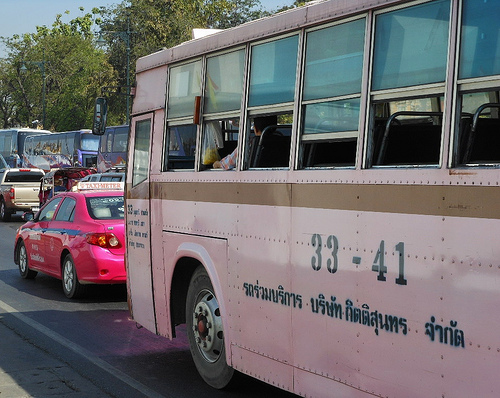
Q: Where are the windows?
A: On the side of the bus.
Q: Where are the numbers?
A: On the side of the bus.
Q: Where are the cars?
A: In the street.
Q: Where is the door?
A: At the front of the bus.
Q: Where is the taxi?
A: In front of the bus.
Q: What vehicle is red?
A: The taxi.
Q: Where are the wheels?
A: On the vehicle.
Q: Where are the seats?
A: Inside the bus.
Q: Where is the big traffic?
A: On a busy street.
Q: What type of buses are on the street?
A: Transit buses.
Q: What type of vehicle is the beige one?
A: A pick up truck.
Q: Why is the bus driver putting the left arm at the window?
A: To rest the arm.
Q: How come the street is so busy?
A: Everyone goes to work at the same time.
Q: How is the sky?
A: Clear and blue.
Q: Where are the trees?
A: Alongside the street.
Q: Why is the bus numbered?
A: To identify the buses easily.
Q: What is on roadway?
A: Pink bus.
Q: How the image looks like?
A: Good.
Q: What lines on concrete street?
A: White.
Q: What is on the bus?
A: Numbers.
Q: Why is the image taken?
A: Remembrance.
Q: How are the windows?
A: Opened.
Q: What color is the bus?
A: White.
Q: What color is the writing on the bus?
A: Green.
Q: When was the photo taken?
A: Day time.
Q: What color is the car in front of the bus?
A: Red.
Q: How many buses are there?
A: One.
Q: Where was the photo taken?
A: A city street.